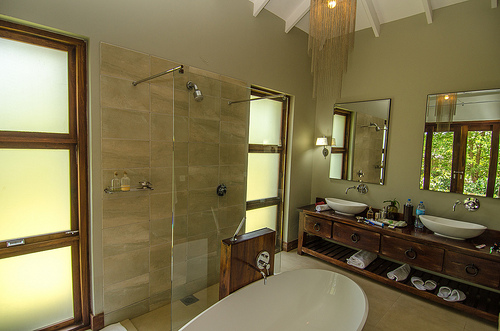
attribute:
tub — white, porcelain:
[230, 267, 367, 329]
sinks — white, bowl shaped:
[323, 196, 487, 238]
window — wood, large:
[245, 88, 294, 227]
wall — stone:
[2, 18, 324, 264]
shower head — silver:
[187, 80, 206, 107]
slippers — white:
[439, 285, 465, 301]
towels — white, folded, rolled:
[344, 246, 378, 273]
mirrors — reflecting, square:
[334, 88, 498, 186]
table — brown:
[306, 199, 494, 304]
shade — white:
[316, 134, 326, 148]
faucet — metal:
[347, 184, 357, 194]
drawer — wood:
[382, 241, 434, 269]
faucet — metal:
[255, 246, 269, 283]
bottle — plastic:
[413, 197, 427, 232]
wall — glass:
[172, 65, 242, 179]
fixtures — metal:
[196, 181, 230, 202]